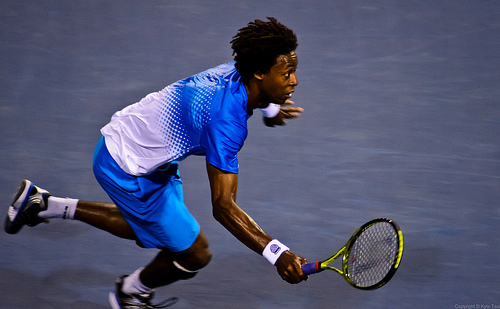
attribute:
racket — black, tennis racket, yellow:
[300, 217, 405, 291]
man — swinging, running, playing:
[3, 15, 309, 308]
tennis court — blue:
[3, 2, 500, 309]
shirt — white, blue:
[100, 61, 252, 177]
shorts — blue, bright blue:
[91, 134, 201, 253]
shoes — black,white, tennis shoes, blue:
[4, 179, 179, 309]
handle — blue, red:
[301, 261, 323, 276]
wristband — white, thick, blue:
[262, 238, 291, 266]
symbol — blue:
[269, 243, 283, 254]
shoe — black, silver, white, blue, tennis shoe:
[4, 178, 51, 234]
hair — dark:
[229, 15, 299, 84]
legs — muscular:
[54, 179, 213, 288]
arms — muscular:
[204, 103, 284, 261]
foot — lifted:
[3, 178, 53, 234]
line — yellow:
[392, 229, 405, 269]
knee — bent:
[173, 240, 213, 275]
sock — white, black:
[37, 196, 79, 221]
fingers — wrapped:
[283, 257, 308, 285]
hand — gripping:
[276, 252, 308, 285]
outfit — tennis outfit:
[92, 61, 249, 252]